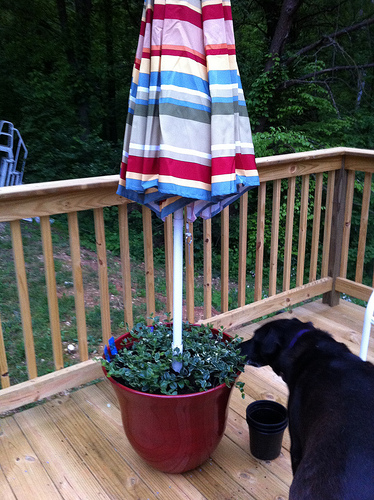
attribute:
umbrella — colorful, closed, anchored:
[116, 1, 262, 222]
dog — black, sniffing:
[240, 319, 371, 499]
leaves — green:
[99, 311, 250, 395]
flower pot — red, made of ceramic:
[99, 322, 247, 476]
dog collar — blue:
[275, 325, 330, 379]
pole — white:
[173, 163, 185, 367]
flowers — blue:
[99, 334, 123, 368]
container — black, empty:
[245, 398, 291, 463]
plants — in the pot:
[100, 303, 253, 399]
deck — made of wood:
[4, 149, 372, 495]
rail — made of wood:
[0, 147, 371, 407]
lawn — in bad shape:
[9, 43, 371, 374]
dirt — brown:
[0, 237, 251, 331]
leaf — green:
[239, 382, 247, 399]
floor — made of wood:
[0, 298, 371, 499]